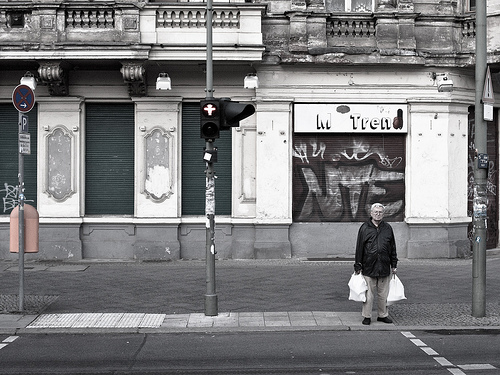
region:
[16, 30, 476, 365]
The person is waiting to cross the street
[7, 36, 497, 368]
The person is waiting for traffic to pass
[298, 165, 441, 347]
The person is carrying two bags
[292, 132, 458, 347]
The person has done some shopping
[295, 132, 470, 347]
The person is now returning home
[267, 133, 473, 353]
The person is bringing food home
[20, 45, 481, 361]
The person is in a city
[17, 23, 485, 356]
The person has been to a store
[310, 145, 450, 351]
A person is standing on the sidewalk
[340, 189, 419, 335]
A person is wearing a dark coat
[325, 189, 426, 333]
man standing near the street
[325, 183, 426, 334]
older man standing near the street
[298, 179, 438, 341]
mature man standing near the street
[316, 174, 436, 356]
business man standing near the street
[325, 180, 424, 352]
gentleman standing near the street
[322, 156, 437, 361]
distinguished man standing near the street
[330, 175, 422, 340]
man standing near the street with bags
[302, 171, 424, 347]
man standing near the street holding bags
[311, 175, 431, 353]
older man standing near the street with bags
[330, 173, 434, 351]
mature man standing near the street with bags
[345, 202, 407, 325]
a man carrying groceries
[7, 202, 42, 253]
a red container attached to a pole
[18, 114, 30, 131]
a parking sign on a pole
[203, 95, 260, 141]
a foreign street light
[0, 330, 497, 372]
a dark gray street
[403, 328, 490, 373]
a row of striped white lines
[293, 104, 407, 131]
a sign to a shop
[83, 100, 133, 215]
green shutters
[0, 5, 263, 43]
black and white railings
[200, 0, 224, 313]
a long pole with street lights on it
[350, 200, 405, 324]
The man is holding white bags.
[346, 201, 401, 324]
The man is wearing a black coat.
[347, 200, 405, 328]
The man is wearing black shoes.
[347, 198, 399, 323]
The man is wearing tan pants.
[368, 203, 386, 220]
The man's hair is short.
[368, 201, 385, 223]
The man's hair is white.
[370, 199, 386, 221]
The man is wearing glasses.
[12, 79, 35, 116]
The sign is red and blue.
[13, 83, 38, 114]
The sign is round.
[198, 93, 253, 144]
The stop light fixture is black.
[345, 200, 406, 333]
Man about to cross a street.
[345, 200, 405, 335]
Man carrying three white bags.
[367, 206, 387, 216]
Man wearing a pair of eyeglasses.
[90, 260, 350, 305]
Sidewalk is paved.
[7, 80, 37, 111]
Blue and red street sign on the sidewalk.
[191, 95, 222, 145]
Pedestrians crossing light on the sidewalk.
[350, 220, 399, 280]
Man wearing black leather jacket.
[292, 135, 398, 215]
Graffitis on the metallic store window blind.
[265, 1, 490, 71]
Front face of the balcony is damaged.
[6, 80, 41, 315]
Street sign hanging on a metallic pole.